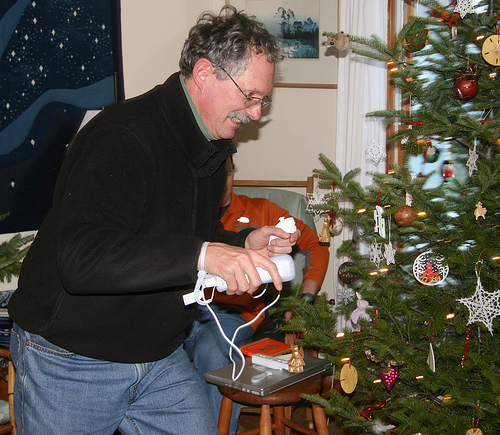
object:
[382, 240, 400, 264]
star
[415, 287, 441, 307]
leafs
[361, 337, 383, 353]
leafs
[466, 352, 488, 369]
leafs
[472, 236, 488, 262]
leafs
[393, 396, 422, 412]
leafs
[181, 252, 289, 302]
wii remote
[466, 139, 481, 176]
snowflake ornament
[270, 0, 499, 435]
christmas tree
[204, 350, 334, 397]
laptop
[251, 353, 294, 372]
controller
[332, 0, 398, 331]
curtain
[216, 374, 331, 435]
stool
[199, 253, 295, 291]
machine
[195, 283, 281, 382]
cord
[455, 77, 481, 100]
apple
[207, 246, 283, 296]
hand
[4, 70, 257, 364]
black sweater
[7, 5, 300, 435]
man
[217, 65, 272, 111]
eyeglasses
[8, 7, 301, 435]
adult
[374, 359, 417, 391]
ornament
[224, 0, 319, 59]
image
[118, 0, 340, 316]
wall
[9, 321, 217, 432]
jeans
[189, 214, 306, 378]
video game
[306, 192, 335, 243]
ornaments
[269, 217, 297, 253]
controller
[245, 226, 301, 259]
hand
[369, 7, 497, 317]
window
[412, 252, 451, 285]
ornament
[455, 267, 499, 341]
ornament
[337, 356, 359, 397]
ornament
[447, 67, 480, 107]
ornament